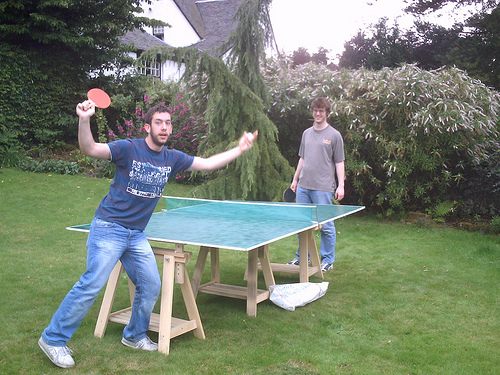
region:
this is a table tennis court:
[158, 184, 367, 330]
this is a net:
[206, 200, 317, 222]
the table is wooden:
[252, 255, 324, 305]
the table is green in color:
[177, 225, 239, 237]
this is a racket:
[84, 85, 115, 108]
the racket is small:
[77, 89, 113, 109]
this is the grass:
[363, 238, 452, 350]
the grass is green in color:
[359, 247, 481, 366]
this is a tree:
[9, 10, 53, 177]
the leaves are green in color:
[1, 22, 50, 119]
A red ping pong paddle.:
[76, 87, 109, 116]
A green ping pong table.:
[63, 192, 364, 252]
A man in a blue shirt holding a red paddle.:
[37, 96, 259, 368]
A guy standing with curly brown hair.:
[310, 94, 335, 124]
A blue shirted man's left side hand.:
[238, 130, 260, 152]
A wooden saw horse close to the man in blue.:
[89, 234, 208, 354]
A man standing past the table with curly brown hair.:
[288, 95, 344, 272]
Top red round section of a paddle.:
[85, 87, 111, 108]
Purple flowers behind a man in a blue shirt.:
[101, 84, 206, 184]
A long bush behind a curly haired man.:
[269, 56, 499, 218]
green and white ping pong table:
[56, 191, 372, 252]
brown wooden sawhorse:
[100, 237, 210, 362]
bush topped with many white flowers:
[269, 60, 499, 235]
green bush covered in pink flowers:
[106, 83, 205, 185]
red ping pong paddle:
[71, 77, 116, 122]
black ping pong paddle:
[281, 181, 298, 207]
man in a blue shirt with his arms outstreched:
[26, 78, 261, 371]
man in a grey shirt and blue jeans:
[281, 90, 361, 276]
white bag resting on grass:
[266, 272, 331, 315]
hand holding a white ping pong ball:
[234, 125, 266, 155]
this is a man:
[79, 110, 171, 346]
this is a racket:
[86, 88, 119, 108]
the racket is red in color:
[92, 87, 108, 94]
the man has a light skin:
[87, 140, 104, 155]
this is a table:
[187, 197, 263, 257]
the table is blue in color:
[185, 207, 224, 243]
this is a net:
[177, 195, 300, 217]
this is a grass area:
[366, 240, 462, 355]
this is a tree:
[386, 67, 454, 209]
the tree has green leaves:
[5, 49, 55, 100]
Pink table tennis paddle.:
[82, 87, 109, 113]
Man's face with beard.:
[140, 102, 171, 149]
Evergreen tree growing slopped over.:
[129, 45, 292, 200]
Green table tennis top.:
[63, 200, 372, 257]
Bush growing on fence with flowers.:
[283, 63, 498, 208]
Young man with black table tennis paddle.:
[280, 99, 344, 272]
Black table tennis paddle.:
[282, 184, 294, 201]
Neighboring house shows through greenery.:
[81, 22, 191, 92]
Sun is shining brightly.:
[272, 9, 358, 57]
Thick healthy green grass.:
[0, 172, 50, 319]